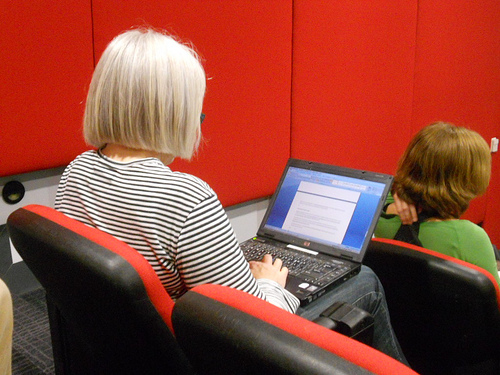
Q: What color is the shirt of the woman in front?
A: Green.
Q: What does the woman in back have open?
A: A laptop.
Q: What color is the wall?
A: Red.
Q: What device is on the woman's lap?
A: Laptop computer.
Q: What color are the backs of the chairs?
A: Black.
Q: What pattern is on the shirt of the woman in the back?
A: Stripes.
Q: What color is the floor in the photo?
A: Black.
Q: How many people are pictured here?
A: Two.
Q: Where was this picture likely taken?
A: A lecture hall.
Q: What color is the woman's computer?
A: Black.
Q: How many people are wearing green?
A: One.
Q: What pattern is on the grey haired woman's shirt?
A: Stripes.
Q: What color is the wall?
A: Red.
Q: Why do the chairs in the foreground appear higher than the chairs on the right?
A: The chairs are set up in tiers.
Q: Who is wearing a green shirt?
A: Blonde person on the right?.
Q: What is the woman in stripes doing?
A: Using a laptop.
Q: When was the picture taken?
A: During a lecture.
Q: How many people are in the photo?
A: 2.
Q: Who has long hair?
A: No one.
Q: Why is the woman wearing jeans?
A: To be comfortable.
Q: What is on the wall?
A: Red padding.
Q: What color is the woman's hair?
A: Grey.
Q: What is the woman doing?
A: Typing.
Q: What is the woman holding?
A: A laptop.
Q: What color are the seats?
A: Red and black.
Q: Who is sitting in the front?
A: A woman in a green shirt.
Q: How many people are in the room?
A: 2.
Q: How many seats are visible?
A: 3.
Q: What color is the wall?
A: Red.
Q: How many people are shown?
A: Two.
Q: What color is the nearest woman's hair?
A: Grey.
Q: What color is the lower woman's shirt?
A: Green.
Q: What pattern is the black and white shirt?
A: Stripes.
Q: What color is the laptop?
A: Black.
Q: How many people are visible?
A: Two.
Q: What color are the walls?
A: Red.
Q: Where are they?
A: A classroom.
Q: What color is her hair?
A: White.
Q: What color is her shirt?
A: Black and white.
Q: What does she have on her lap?
A: Laptop.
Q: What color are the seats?
A: Red and black.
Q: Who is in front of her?
A: Another lady.